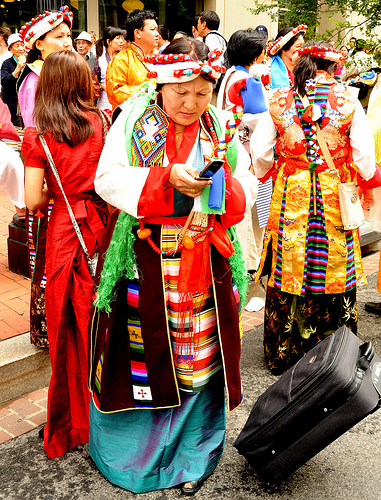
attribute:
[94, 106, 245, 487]
costume — colorful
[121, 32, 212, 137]
woman — texting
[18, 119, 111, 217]
shirt — red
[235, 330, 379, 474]
suitcase — black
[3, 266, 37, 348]
floor — orange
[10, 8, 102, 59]
headdress — colorful